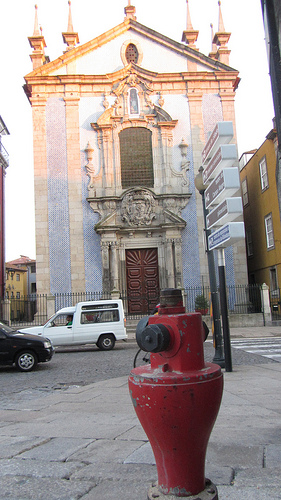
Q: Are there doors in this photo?
A: Yes, there is a door.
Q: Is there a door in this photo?
A: Yes, there is a door.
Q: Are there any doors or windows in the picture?
A: Yes, there is a door.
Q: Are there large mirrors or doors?
A: Yes, there is a large door.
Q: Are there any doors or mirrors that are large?
A: Yes, the door is large.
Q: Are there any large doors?
A: Yes, there is a large door.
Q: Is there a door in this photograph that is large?
A: Yes, there is a door that is large.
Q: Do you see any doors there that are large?
A: Yes, there is a door that is large.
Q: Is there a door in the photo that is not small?
A: Yes, there is a large door.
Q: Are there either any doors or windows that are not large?
A: No, there is a door but it is large.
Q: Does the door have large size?
A: Yes, the door is large.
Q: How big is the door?
A: The door is large.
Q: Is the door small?
A: No, the door is large.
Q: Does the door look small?
A: No, the door is large.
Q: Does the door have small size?
A: No, the door is large.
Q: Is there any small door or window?
A: No, there is a door but it is large.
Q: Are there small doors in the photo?
A: No, there is a door but it is large.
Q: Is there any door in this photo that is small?
A: No, there is a door but it is large.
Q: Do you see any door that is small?
A: No, there is a door but it is large.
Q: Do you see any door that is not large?
A: No, there is a door but it is large.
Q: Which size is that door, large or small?
A: The door is large.